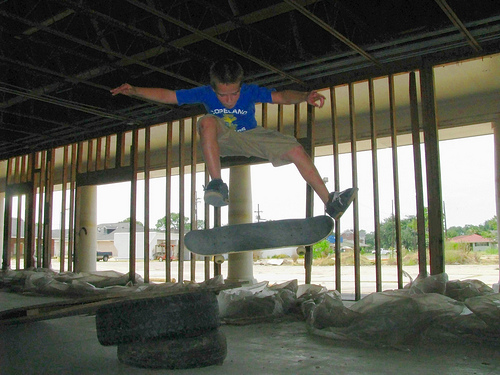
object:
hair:
[208, 59, 244, 93]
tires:
[114, 329, 232, 372]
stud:
[417, 64, 445, 276]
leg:
[198, 114, 227, 181]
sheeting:
[5, 265, 499, 357]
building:
[2, 5, 500, 304]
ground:
[349, 110, 416, 176]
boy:
[106, 57, 358, 223]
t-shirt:
[173, 81, 273, 133]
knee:
[195, 115, 215, 137]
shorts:
[194, 114, 302, 168]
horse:
[219, 110, 240, 130]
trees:
[372, 207, 444, 257]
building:
[443, 228, 498, 255]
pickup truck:
[92, 249, 114, 264]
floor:
[1, 286, 497, 373]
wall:
[384, 74, 404, 297]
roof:
[442, 230, 499, 244]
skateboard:
[183, 215, 336, 263]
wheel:
[212, 252, 225, 265]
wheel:
[295, 246, 308, 257]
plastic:
[218, 270, 498, 355]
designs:
[209, 107, 248, 132]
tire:
[94, 290, 222, 349]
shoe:
[201, 179, 230, 208]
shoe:
[325, 186, 360, 222]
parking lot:
[0, 253, 500, 293]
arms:
[133, 81, 212, 106]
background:
[0, 0, 498, 268]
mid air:
[133, 174, 372, 274]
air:
[450, 151, 483, 189]